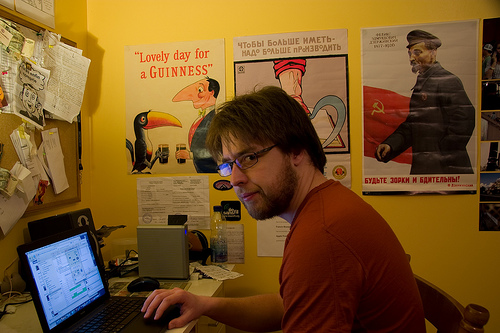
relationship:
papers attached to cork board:
[0, 33, 85, 119] [51, 123, 90, 160]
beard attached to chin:
[264, 192, 277, 203] [249, 207, 264, 218]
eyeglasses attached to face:
[215, 155, 256, 172] [205, 123, 289, 216]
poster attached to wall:
[354, 29, 470, 197] [134, 0, 176, 20]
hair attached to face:
[229, 109, 267, 127] [205, 123, 289, 216]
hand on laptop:
[139, 288, 206, 327] [24, 235, 160, 329]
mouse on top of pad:
[129, 279, 148, 291] [105, 277, 126, 295]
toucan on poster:
[125, 109, 183, 175] [354, 29, 470, 197]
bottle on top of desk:
[210, 211, 227, 268] [201, 280, 217, 288]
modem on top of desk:
[134, 226, 182, 281] [201, 280, 217, 288]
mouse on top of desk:
[129, 279, 148, 291] [201, 280, 217, 288]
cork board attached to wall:
[51, 123, 90, 160] [134, 0, 176, 20]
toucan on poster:
[127, 106, 176, 167] [354, 29, 470, 197]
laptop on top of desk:
[24, 235, 160, 329] [201, 280, 217, 288]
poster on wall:
[354, 29, 470, 197] [134, 0, 176, 20]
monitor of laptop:
[32, 242, 96, 308] [24, 235, 160, 329]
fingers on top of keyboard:
[141, 303, 164, 318] [104, 310, 134, 325]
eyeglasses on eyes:
[215, 155, 256, 172] [235, 149, 259, 164]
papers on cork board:
[0, 33, 85, 119] [51, 123, 90, 160]